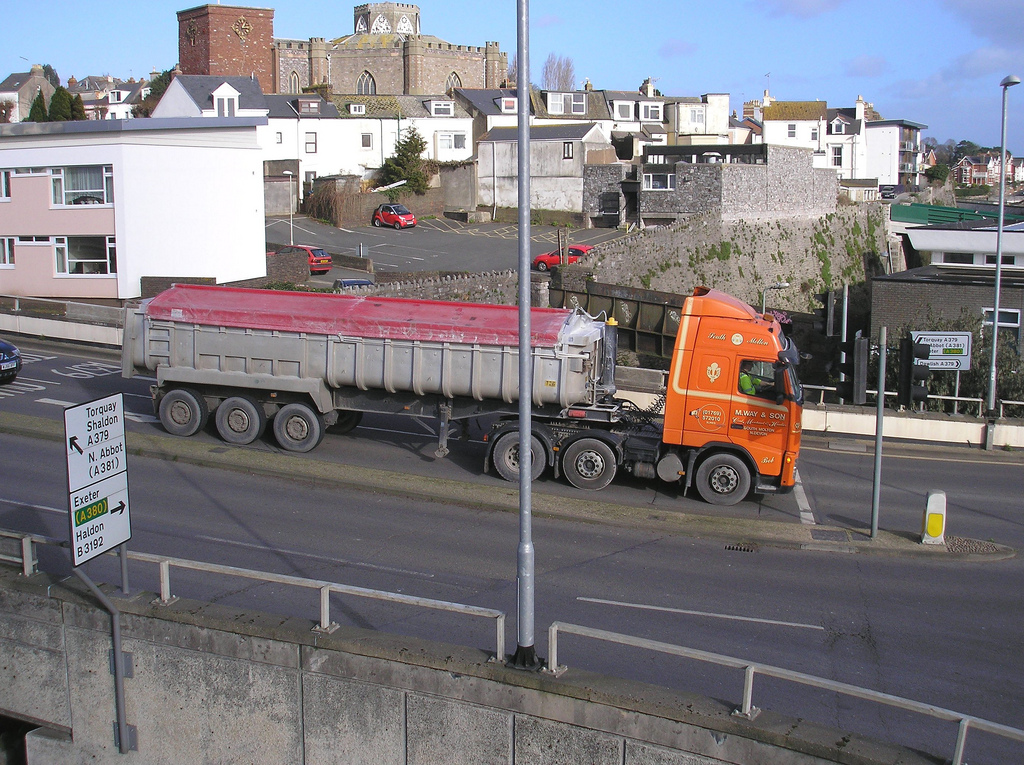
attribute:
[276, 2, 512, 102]
building — Large 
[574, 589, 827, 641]
lines — White 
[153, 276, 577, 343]
tarp — Red 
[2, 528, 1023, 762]
rails — Metal , gray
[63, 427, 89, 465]
arrow — black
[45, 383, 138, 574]
signboard — white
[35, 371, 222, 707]
signboard — white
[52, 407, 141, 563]
sign — street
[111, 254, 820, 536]
truck — large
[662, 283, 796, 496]
cab — Orange 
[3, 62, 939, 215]
houses — bunch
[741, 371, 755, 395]
shirt — fluorescent green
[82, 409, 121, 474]
letters — black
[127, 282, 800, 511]
truck — large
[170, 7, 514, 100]
castle — big, gray, bricked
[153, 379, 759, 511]
wheels — dark